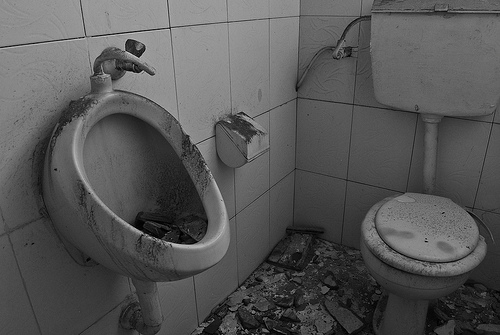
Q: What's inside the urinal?
A: Rocks.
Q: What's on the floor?
A: Ruble.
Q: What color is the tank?
A: White.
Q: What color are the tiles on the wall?
A: White.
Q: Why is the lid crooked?
A: It's broke.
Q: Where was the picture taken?
A: In a bathroom.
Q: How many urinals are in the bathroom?
A: 1.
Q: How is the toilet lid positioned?
A: Closed.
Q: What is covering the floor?
A: Broken tile.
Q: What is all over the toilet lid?
A: Dirt.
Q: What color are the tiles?
A: White.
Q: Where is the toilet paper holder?
A: On wall.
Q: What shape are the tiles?
A: Square.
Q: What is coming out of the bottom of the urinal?
A: A pipe.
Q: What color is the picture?
A: Black and white.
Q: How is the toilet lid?
A: Closed.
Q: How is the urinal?
A: Dirty.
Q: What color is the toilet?
A: White.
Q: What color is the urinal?
A: White.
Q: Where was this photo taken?
A: In an old bathroom.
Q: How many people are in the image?
A: None.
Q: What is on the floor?
A: Broken tile and debris.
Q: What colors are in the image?
A: Black, white, and gray.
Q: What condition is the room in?
A: Broken and dirty.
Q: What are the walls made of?
A: Tiles.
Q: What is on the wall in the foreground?
A: A urinal.